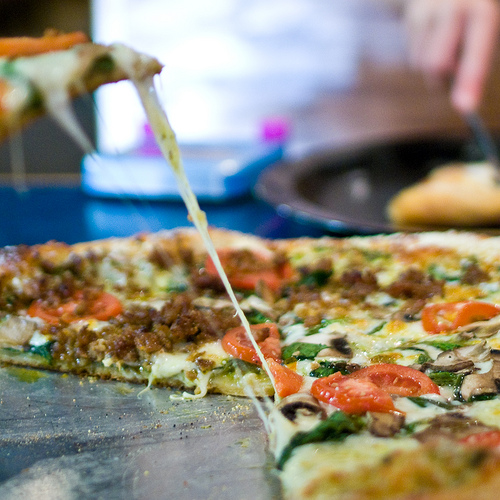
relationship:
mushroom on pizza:
[281, 391, 329, 423] [1, 223, 497, 494]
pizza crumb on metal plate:
[186, 420, 193, 429] [0, 362, 280, 499]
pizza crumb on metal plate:
[167, 422, 179, 429] [0, 362, 280, 499]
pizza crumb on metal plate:
[139, 465, 152, 479] [0, 362, 280, 499]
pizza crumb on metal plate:
[67, 395, 82, 405] [0, 362, 280, 499]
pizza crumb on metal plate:
[226, 402, 238, 417] [0, 362, 280, 499]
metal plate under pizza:
[0, 355, 280, 498] [1, 223, 497, 494]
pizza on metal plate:
[1, 223, 497, 494] [0, 362, 280, 499]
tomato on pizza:
[309, 359, 444, 415] [1, 223, 497, 494]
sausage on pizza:
[55, 297, 242, 359] [1, 223, 497, 494]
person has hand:
[402, 1, 499, 129] [405, 1, 500, 130]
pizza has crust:
[1, 223, 497, 494] [29, 201, 497, 266]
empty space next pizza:
[4, 375, 270, 497] [193, 180, 355, 369]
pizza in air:
[0, 26, 163, 129] [1, 3, 498, 179]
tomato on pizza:
[420, 290, 499, 333] [1, 223, 497, 494]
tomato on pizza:
[214, 312, 289, 367] [1, 223, 497, 494]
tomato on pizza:
[199, 238, 297, 291] [1, 223, 497, 494]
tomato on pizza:
[18, 279, 127, 323] [1, 223, 497, 494]